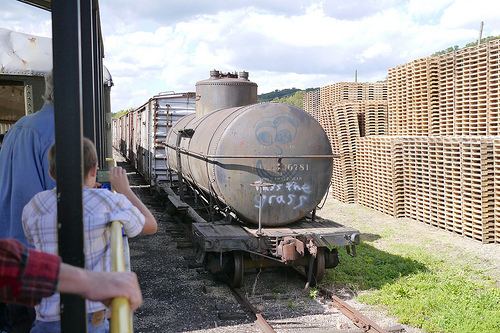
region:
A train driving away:
[117, 67, 380, 315]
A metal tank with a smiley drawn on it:
[173, 67, 336, 231]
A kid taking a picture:
[25, 142, 152, 332]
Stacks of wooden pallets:
[300, 31, 499, 250]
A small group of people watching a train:
[2, 67, 156, 331]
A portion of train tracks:
[211, 272, 403, 329]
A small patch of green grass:
[352, 249, 499, 327]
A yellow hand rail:
[108, 209, 140, 331]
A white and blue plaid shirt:
[15, 187, 146, 319]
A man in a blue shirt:
[0, 59, 56, 248]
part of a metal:
[254, 135, 291, 174]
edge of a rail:
[228, 290, 240, 312]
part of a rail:
[262, 297, 313, 319]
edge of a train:
[212, 173, 227, 210]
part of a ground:
[410, 289, 430, 320]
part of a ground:
[164, 273, 178, 288]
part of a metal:
[246, 182, 287, 258]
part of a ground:
[411, 280, 439, 319]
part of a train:
[266, 115, 289, 146]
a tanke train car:
[159, 72, 362, 282]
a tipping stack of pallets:
[318, 102, 357, 204]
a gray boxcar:
[130, 92, 195, 186]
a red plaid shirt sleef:
[0, 235, 60, 301]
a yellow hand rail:
[104, 155, 131, 332]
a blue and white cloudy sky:
[102, 3, 495, 110]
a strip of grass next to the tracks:
[332, 243, 498, 329]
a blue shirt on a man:
[2, 103, 58, 249]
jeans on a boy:
[32, 306, 109, 331]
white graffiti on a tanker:
[252, 177, 310, 215]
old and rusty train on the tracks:
[107, 68, 354, 285]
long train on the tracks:
[107, 68, 354, 289]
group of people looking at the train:
[0, 68, 160, 329]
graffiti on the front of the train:
[228, 109, 323, 209]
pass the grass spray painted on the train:
[250, 180, 313, 214]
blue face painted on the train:
[250, 115, 302, 184]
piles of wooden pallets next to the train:
[302, 48, 498, 248]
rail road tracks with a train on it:
[112, 135, 390, 331]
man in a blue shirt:
[0, 70, 87, 245]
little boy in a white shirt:
[20, 139, 157, 326]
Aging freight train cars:
[114, 83, 376, 265]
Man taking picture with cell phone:
[21, 128, 183, 313]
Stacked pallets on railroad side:
[301, 83, 499, 247]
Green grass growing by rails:
[335, 215, 460, 330]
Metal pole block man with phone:
[48, 8, 113, 329]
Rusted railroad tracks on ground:
[226, 274, 386, 331]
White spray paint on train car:
[238, 170, 322, 215]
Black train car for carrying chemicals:
[167, 88, 348, 230]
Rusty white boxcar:
[121, 93, 200, 195]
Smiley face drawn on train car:
[246, 116, 326, 183]